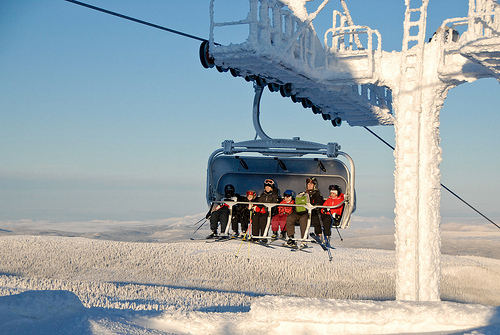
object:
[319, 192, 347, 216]
jacket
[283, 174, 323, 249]
person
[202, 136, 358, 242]
lift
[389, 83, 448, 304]
pillar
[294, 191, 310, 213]
backpack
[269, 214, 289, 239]
pants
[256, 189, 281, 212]
coat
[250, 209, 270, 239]
bottom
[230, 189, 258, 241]
child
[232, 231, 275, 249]
ski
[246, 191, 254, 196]
goggle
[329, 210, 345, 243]
pole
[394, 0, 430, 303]
ladder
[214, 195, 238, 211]
shirt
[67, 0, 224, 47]
cable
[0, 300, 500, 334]
ground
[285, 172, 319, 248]
skier